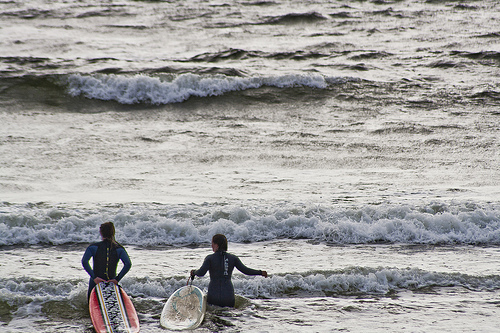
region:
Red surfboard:
[85, 275, 138, 331]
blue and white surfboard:
[162, 283, 214, 331]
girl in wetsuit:
[87, 217, 139, 286]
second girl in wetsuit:
[198, 230, 248, 317]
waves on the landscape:
[22, 181, 268, 242]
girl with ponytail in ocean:
[82, 225, 143, 292]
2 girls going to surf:
[87, 215, 254, 328]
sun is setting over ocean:
[21, 17, 382, 189]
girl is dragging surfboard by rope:
[162, 235, 263, 331]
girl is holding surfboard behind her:
[85, 218, 189, 331]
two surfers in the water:
[42, 181, 372, 328]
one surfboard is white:
[144, 208, 269, 328]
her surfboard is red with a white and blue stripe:
[50, 203, 149, 329]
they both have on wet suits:
[62, 203, 259, 306]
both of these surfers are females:
[31, 183, 292, 330]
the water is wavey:
[15, 6, 489, 303]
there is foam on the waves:
[8, 195, 498, 252]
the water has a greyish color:
[21, 9, 486, 196]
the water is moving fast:
[6, 24, 266, 313]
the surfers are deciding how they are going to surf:
[66, 201, 267, 286]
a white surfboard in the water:
[158, 283, 213, 331]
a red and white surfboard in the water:
[85, 281, 145, 329]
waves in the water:
[294, 193, 467, 264]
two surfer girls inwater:
[75, 218, 252, 307]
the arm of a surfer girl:
[234, 253, 274, 281]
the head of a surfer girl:
[93, 219, 126, 247]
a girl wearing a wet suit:
[186, 229, 273, 310]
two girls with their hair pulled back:
[92, 217, 236, 264]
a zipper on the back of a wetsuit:
[96, 243, 117, 280]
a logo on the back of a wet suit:
[220, 254, 237, 282]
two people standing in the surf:
[59, 191, 251, 331]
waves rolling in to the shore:
[15, 180, 312, 332]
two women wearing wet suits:
[55, 211, 275, 320]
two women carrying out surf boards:
[44, 213, 277, 331]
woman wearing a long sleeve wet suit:
[178, 233, 271, 331]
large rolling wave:
[49, 36, 381, 173]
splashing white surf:
[284, 188, 486, 305]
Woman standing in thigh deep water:
[164, 200, 256, 332]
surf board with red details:
[64, 256, 154, 328]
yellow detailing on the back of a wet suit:
[93, 228, 129, 284]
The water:
[317, 110, 389, 285]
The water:
[347, 149, 385, 249]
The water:
[317, 134, 358, 247]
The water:
[336, 144, 412, 314]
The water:
[326, 194, 379, 330]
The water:
[376, 150, 408, 288]